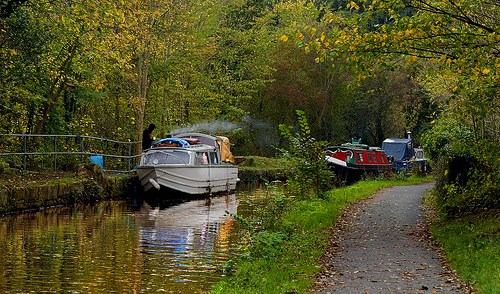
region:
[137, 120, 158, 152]
person in a black hooded sweat shirt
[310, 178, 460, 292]
asphalt paved foot path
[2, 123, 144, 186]
black painted metal guard rail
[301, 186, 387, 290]
dead leaves lining the edge of a path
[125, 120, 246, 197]
small covered river boat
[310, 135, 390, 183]
small red covered river boat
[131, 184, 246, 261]
reflection of a boat in the water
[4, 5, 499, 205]
densely forested area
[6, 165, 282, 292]
calm reflective river water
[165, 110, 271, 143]
grey smoke coming from a boat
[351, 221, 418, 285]
leaves on the sidewalk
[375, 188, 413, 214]
the sidewalk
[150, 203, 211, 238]
reflection on the water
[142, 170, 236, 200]
a boat in the water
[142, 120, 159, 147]
a person standing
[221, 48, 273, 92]
the leaves are green on the tree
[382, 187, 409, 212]
the sidewalk is grey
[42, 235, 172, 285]
the water in the lake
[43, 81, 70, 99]
tree branches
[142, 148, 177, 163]
windshield on the boat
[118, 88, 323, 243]
Boat on the water.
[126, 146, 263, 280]
Reflection in the water.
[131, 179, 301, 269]
Water by the path.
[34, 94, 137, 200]
Fence by the boat.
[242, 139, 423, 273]
Grass by the water.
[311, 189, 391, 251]
Leaves on the road.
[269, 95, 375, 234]
Bush by the road.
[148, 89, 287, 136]
Smoke above the boat.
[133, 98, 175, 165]
Person by the boat.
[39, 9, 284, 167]
Tree in the background.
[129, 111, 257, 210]
a boat traveling on a river.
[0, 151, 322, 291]
A river filled with water.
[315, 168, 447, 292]
a sidewalk covered in leaves.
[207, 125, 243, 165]
the back of a boat.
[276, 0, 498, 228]
a tree filled with flowers.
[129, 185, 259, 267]
reflection of a boat on a river.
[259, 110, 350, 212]
trees on a river.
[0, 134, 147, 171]
Metal bar fence.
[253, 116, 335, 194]
A large green brush.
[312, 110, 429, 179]
a parked boat.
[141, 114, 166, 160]
A person standing by the boat.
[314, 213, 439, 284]
Brown leaves on the ground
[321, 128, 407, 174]
A red boat in the water.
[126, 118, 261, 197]
A white boat in the canal.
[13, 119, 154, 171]
A gate on the side of boat.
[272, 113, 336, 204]
A tree on the edge of sidewalk.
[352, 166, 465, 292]
A walkway by the water.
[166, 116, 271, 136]
Smoke coming from the boat.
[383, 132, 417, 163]
A cover over the object.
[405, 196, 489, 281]
The grass is green.